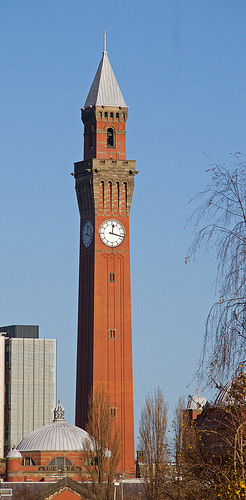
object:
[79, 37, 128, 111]
roof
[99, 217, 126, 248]
clock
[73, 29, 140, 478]
tower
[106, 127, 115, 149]
window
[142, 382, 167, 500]
tree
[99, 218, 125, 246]
time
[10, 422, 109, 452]
dome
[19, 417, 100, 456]
round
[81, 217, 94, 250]
clock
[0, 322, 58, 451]
building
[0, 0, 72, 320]
sky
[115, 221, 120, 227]
numbers